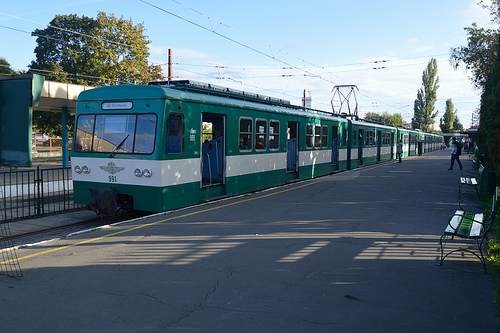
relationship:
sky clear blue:
[306, 2, 386, 41] [332, 5, 388, 35]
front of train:
[60, 79, 178, 218] [55, 80, 425, 221]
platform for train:
[179, 180, 400, 273] [55, 80, 425, 221]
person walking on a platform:
[444, 135, 468, 173] [179, 180, 400, 273]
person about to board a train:
[393, 136, 406, 163] [55, 80, 425, 221]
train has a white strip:
[55, 80, 425, 221] [65, 156, 165, 193]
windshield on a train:
[74, 113, 153, 153] [55, 80, 425, 221]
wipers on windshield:
[104, 134, 132, 155] [74, 113, 153, 153]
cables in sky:
[362, 52, 415, 73] [306, 2, 386, 41]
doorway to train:
[197, 107, 230, 187] [55, 80, 425, 221]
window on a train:
[165, 111, 185, 156] [55, 80, 425, 221]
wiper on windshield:
[104, 134, 132, 155] [74, 113, 153, 153]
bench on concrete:
[453, 161, 490, 194] [418, 180, 447, 211]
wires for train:
[282, 53, 323, 82] [55, 80, 425, 221]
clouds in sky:
[458, 2, 476, 17] [306, 2, 386, 41]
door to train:
[197, 107, 230, 187] [55, 80, 425, 221]